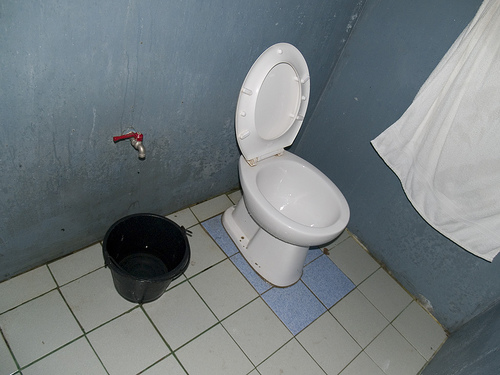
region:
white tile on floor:
[0, 269, 55, 308]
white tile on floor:
[3, 286, 80, 363]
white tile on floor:
[22, 335, 109, 372]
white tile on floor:
[83, 306, 170, 373]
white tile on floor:
[60, 265, 140, 335]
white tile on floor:
[141, 280, 219, 349]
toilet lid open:
[208, 22, 358, 295]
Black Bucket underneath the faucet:
[91, 209, 214, 321]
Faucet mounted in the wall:
[94, 105, 163, 169]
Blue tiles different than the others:
[198, 190, 375, 338]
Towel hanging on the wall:
[362, 41, 499, 309]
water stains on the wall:
[5, 58, 233, 238]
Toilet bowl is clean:
[243, 152, 364, 259]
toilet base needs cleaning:
[221, 210, 296, 303]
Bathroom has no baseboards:
[5, 10, 499, 373]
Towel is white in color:
[363, 10, 498, 272]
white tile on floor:
[9, 281, 71, 311]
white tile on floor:
[198, 251, 263, 326]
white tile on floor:
[234, 300, 283, 370]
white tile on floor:
[338, 276, 391, 348]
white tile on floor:
[403, 305, 447, 349]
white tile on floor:
[296, 326, 356, 373]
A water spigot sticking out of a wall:
[113, 121, 149, 167]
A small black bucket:
[103, 210, 190, 304]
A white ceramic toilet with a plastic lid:
[220, 42, 351, 289]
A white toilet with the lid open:
[221, 40, 351, 288]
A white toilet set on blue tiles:
[201, 43, 356, 339]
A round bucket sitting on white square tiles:
[101, 208, 191, 307]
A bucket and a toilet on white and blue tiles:
[101, 40, 351, 304]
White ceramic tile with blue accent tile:
[2, 187, 449, 372]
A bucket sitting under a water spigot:
[102, 129, 191, 302]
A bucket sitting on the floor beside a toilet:
[102, 42, 351, 302]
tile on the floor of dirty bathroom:
[260, 273, 330, 337]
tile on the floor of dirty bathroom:
[218, 294, 295, 367]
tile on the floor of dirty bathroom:
[137, 279, 219, 349]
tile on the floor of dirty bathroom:
[170, 320, 259, 373]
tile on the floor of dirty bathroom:
[82, 299, 172, 373]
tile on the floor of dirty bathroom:
[1, 280, 84, 368]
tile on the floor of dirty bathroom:
[197, 206, 242, 256]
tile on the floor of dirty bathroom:
[390, 297, 454, 361]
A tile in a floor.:
[141, 275, 242, 362]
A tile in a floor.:
[218, 285, 288, 362]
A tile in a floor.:
[283, 305, 353, 367]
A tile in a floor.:
[324, 279, 386, 339]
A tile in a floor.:
[148, 291, 227, 336]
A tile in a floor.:
[48, 257, 153, 322]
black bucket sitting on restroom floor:
[102, 213, 189, 305]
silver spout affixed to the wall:
[111, 130, 147, 162]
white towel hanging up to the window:
[369, 2, 498, 261]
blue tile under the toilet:
[199, 208, 245, 266]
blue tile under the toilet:
[229, 250, 296, 308]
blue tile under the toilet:
[261, 282, 325, 342]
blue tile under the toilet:
[301, 255, 356, 309]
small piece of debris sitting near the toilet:
[321, 248, 332, 255]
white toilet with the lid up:
[222, 43, 351, 287]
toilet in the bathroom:
[191, 52, 388, 261]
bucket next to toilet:
[78, 185, 213, 319]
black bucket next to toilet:
[38, 189, 210, 362]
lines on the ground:
[164, 287, 292, 360]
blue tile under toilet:
[269, 255, 358, 344]